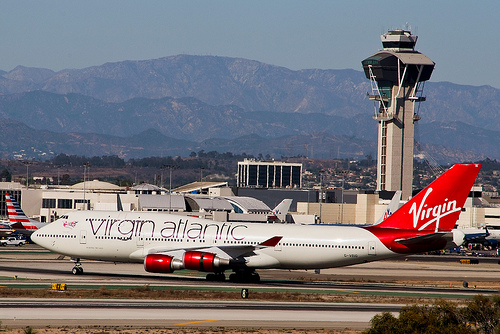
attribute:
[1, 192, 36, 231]
design — white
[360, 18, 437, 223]
tower — watch tower, tall